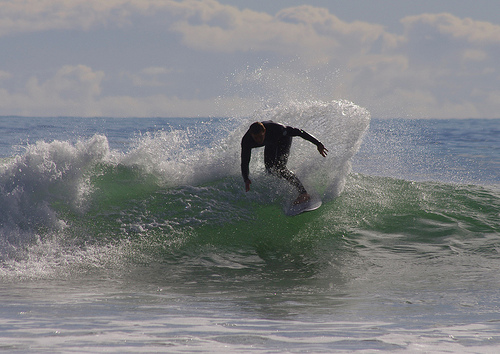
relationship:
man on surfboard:
[241, 120, 330, 204] [242, 170, 341, 215]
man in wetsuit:
[241, 120, 330, 204] [268, 137, 309, 170]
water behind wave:
[1, 94, 498, 351] [1, 100, 499, 284]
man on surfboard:
[241, 120, 330, 204] [291, 174, 326, 217]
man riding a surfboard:
[241, 120, 330, 204] [288, 193, 323, 213]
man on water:
[241, 120, 330, 204] [1, 94, 498, 351]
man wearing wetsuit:
[241, 120, 328, 204] [235, 122, 327, 195]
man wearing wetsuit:
[241, 120, 330, 204] [237, 112, 304, 195]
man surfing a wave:
[241, 120, 330, 204] [14, 115, 486, 248]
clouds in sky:
[1, 0, 498, 117] [0, 1, 497, 120]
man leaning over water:
[241, 120, 330, 204] [1, 94, 498, 351]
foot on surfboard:
[292, 190, 312, 209] [284, 177, 322, 216]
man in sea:
[241, 120, 330, 204] [1, 113, 499, 348]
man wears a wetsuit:
[241, 120, 328, 204] [238, 122, 305, 194]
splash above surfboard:
[273, 83, 370, 143] [291, 188, 331, 224]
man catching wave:
[241, 120, 330, 204] [15, 136, 390, 258]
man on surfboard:
[241, 120, 330, 204] [291, 194, 325, 212]